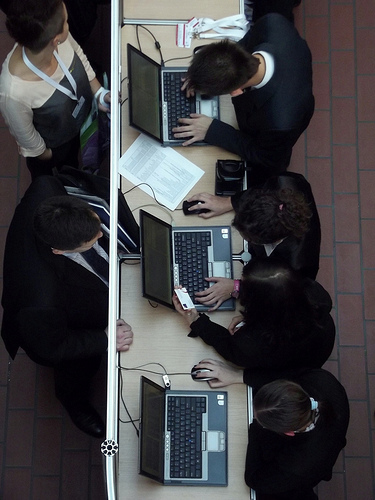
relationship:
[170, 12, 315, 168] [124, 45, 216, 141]
man on laptop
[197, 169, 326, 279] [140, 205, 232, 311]
person on laptop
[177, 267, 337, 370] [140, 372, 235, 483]
person on laptop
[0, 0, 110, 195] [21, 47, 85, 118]
people wears necklace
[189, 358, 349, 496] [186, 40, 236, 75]
man have head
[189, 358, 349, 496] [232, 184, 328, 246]
man have head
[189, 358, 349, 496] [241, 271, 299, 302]
man have head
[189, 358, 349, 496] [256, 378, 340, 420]
man have head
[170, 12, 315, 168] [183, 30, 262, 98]
man have hair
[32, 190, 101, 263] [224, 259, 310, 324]
hair have hair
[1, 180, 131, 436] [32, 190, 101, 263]
man have hair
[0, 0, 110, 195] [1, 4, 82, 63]
people has hair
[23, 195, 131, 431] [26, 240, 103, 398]
man has suit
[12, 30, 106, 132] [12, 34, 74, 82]
band around neck